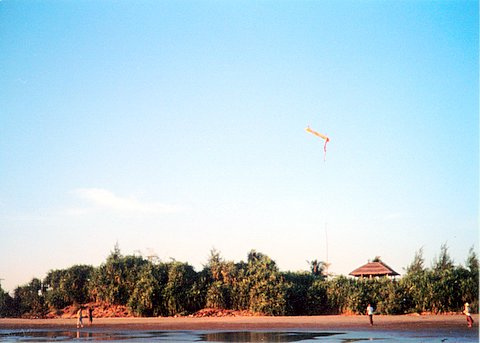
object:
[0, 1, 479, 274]
sky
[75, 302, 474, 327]
people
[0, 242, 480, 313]
trees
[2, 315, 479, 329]
beach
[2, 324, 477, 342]
water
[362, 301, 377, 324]
person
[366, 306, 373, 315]
shirt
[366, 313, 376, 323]
pants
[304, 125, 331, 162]
kite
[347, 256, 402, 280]
building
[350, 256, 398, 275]
roof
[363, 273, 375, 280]
pole